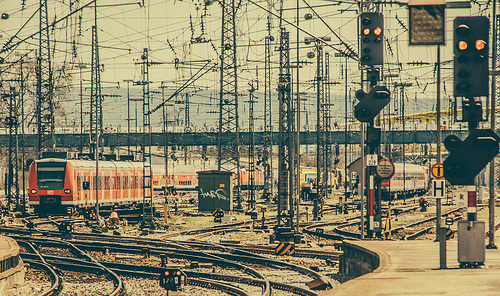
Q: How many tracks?
A: Complex array of them.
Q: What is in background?
A: Wires and towers.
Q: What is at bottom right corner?
A: Platform.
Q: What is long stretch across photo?
A: Pedestrian walkway.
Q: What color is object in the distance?
A: Yellow.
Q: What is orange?
A: Train.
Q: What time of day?
A: Daylight.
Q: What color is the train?
A: Orange and black.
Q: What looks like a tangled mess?
A: The tracks.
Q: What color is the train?
A: Orange.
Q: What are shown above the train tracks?
A: Power lines.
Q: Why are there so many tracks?
A: For multiple trains.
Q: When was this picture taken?
A: During the day.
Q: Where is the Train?
A: On the tracks.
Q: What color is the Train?
A: Orange.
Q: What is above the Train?
A: Cables.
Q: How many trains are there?
A: One.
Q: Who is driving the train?
A: The conductor.